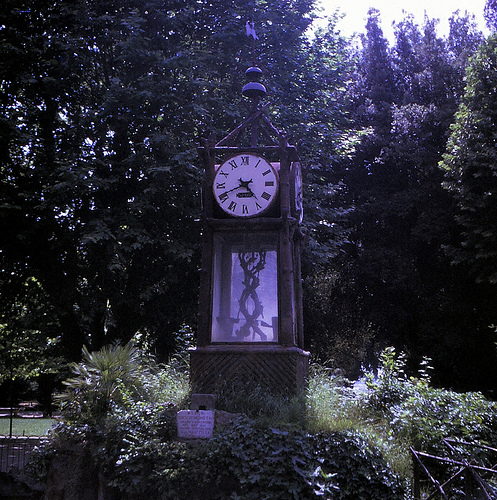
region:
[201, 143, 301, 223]
the face of a clock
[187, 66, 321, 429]
a clock in the outdoors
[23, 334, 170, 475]
greenry surrounded but trees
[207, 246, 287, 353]
a pattern inside a clock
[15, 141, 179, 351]
many trees standing tall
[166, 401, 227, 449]
a sign among the foliage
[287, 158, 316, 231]
a right sided clock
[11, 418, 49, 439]
part of a green lawn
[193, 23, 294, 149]
the top piece of a clock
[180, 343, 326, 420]
the foundation of a clock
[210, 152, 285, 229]
clock's face is white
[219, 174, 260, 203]
clock's hands are black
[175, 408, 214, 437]
a stone sign with engraving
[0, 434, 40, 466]
short metal black fence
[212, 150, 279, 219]
a black and white clock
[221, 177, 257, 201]
hands on the clock face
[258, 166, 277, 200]
roman numerals on the clock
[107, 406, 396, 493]
bush around the clock base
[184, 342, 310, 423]
the base is concrete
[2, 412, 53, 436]
grassy area behind the fence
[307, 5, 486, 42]
sunlight shining through the trees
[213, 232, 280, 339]
glass can be seen through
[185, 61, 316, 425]
a large clock tower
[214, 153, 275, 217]
a black and white clock face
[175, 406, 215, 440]
a small sign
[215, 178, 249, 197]
a clock minute hand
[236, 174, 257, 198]
a clock hour hand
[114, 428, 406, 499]
a section of green ivy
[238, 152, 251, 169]
roman numeral number 12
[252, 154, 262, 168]
roman numeral number 1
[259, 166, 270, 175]
roman numeral number 2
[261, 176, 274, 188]
roman numeral number 3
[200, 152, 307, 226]
clock on the tower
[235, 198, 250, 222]
number on the clock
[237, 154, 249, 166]
number on the clock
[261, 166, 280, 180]
number on the clock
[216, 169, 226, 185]
number on the clock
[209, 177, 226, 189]
number on the clock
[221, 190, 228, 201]
number on the clock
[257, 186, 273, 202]
number on the clock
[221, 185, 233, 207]
number on the clock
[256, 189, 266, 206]
number on the clock